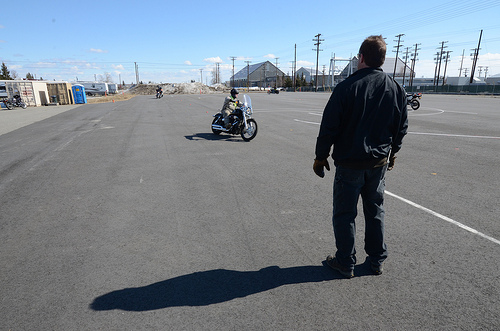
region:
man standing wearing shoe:
[324, 253, 355, 275]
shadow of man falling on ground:
[91, 265, 316, 310]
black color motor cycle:
[212, 109, 259, 140]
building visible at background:
[229, 61, 286, 87]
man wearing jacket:
[328, 80, 407, 159]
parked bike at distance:
[3, 95, 28, 108]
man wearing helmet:
[230, 89, 239, 96]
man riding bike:
[220, 87, 240, 136]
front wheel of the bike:
[242, 120, 256, 139]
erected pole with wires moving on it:
[312, 32, 322, 92]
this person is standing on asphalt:
[305, 15, 425, 287]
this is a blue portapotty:
[65, 73, 96, 103]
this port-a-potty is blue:
[65, 73, 102, 113]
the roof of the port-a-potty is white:
[67, 71, 97, 116]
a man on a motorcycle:
[204, 65, 284, 161]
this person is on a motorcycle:
[182, 44, 294, 182]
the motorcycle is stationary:
[187, 60, 272, 146]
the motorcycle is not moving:
[199, 67, 311, 187]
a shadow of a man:
[80, 238, 351, 329]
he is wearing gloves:
[295, 7, 452, 314]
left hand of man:
[308, 156, 331, 174]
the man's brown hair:
[360, 33, 388, 64]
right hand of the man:
[386, 147, 399, 171]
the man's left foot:
[317, 251, 357, 279]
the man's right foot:
[364, 247, 390, 277]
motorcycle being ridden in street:
[212, 100, 257, 140]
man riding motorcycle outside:
[216, 85, 244, 116]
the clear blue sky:
[13, 4, 240, 48]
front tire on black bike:
[243, 117, 260, 144]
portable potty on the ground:
[68, 82, 88, 103]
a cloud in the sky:
[183, 51, 215, 64]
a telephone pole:
[312, 33, 322, 86]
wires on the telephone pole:
[276, 17, 493, 56]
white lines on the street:
[388, 184, 493, 254]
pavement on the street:
[61, 87, 489, 296]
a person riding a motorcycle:
[211, 86, 256, 139]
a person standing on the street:
[316, 29, 415, 285]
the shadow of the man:
[77, 250, 324, 302]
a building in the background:
[234, 62, 291, 93]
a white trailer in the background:
[85, 79, 115, 94]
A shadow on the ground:
[93, 259, 365, 315]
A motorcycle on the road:
[210, 94, 257, 139]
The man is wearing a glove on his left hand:
[313, 153, 331, 176]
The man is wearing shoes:
[325, 255, 385, 277]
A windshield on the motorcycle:
[238, 94, 251, 109]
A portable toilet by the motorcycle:
[71, 83, 86, 105]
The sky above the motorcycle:
[1, 0, 498, 81]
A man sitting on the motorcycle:
[223, 90, 241, 125]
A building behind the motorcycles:
[230, 59, 285, 87]